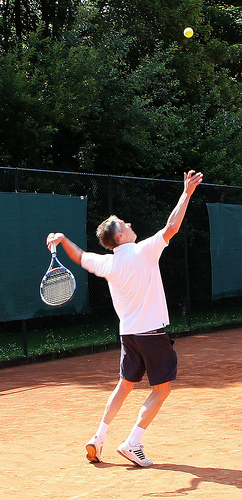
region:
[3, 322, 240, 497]
the tennis court is red clay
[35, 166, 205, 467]
a man is playing tennis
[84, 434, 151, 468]
the man has tennis shoes on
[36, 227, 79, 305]
the tennis racket is in his left hand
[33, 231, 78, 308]
the frame of the racket is blue and white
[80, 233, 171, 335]
the man is wearing a white shirt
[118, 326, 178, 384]
the man is wearing black shorts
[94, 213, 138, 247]
the man has some gray hair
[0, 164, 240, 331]
a green fence is next to the tennis player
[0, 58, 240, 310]
green trees are next to the court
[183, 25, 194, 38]
Neon yellow tennis ball that is in the air.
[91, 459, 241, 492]
Shadow that is cast to the right of a man.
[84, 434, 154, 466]
White tennis shoes with black lines on the sides.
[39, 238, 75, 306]
Blue and white tennis racket in the hand of a man who is serving.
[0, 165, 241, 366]
Large chain linked fence surrounding the play area.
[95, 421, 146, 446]
White socks on a man who is playing tennis.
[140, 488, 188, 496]
Shadow on the ground of a tennis racket.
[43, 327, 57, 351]
Tall weed behind the chain linked fence.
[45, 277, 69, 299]
White strings on a tennis racket.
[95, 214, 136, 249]
Head of a gray haired man serving a tennis ball.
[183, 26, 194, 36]
tennis ball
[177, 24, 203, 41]
green ball in the air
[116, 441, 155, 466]
white tennis shoes on the brown ground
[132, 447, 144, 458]
black stripes on the white shoe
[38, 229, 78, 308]
tennis racket in player's hand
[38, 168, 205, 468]
tennis player swinging racket at the ball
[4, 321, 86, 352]
plants and grass behind the fence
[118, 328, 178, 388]
dark colored shorts on the man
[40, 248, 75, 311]
blue and white tennis racket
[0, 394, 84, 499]
brown dirt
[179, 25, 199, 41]
the yellow tennis ball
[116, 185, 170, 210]
portion of tennis court fence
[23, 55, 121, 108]
portion of tree leaves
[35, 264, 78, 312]
middle portion of tennis racket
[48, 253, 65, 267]
middle portion of tennis racket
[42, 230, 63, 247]
man's hand holding racket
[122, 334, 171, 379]
the man's black shorts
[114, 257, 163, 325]
back part of man's white shirt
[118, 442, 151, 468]
man's foot wearing athletic shoe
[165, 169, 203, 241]
man's hand raised in air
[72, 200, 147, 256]
The man has hair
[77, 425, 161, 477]
The man is wearing shoes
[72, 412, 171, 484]
The man is wearing white and black shoes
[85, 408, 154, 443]
The man is wearing socks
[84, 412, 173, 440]
The man is wearing white socks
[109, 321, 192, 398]
The man is wearing shorts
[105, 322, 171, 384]
The man is wearing black shorts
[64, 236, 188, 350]
The man is wearing a shirt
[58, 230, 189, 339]
The man is wearing a white shirt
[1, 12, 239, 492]
The picture was taken outside